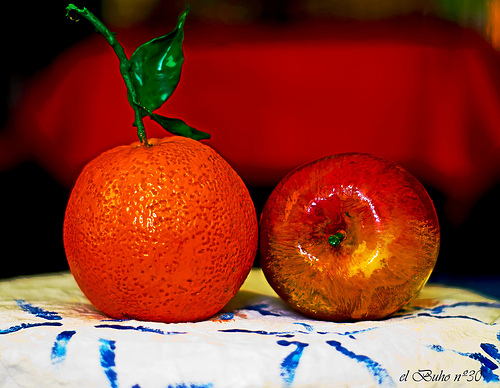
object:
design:
[1, 294, 186, 388]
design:
[219, 300, 395, 387]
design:
[390, 298, 499, 327]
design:
[423, 330, 500, 384]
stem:
[327, 229, 344, 248]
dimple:
[184, 277, 192, 283]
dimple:
[199, 204, 205, 211]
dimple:
[158, 215, 164, 222]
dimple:
[140, 268, 145, 273]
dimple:
[110, 204, 116, 209]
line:
[325, 338, 396, 386]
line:
[275, 337, 310, 386]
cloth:
[0, 268, 500, 387]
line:
[97, 336, 118, 386]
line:
[315, 325, 380, 338]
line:
[92, 322, 187, 336]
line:
[50, 330, 75, 365]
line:
[0, 318, 61, 335]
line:
[11, 296, 61, 319]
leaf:
[126, 3, 191, 117]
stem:
[63, 3, 150, 143]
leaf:
[145, 111, 213, 142]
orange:
[57, 1, 259, 321]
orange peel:
[64, 131, 258, 321]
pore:
[185, 148, 193, 155]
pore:
[169, 190, 176, 196]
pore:
[157, 251, 163, 256]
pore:
[100, 250, 106, 254]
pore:
[110, 204, 116, 208]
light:
[101, 170, 182, 248]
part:
[297, 273, 358, 316]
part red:
[261, 151, 440, 247]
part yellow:
[350, 242, 392, 275]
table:
[1, 265, 498, 387]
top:
[133, 137, 150, 152]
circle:
[63, 134, 257, 319]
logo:
[395, 366, 484, 382]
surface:
[1, 267, 498, 387]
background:
[0, 0, 500, 387]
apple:
[255, 151, 443, 323]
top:
[315, 218, 358, 256]